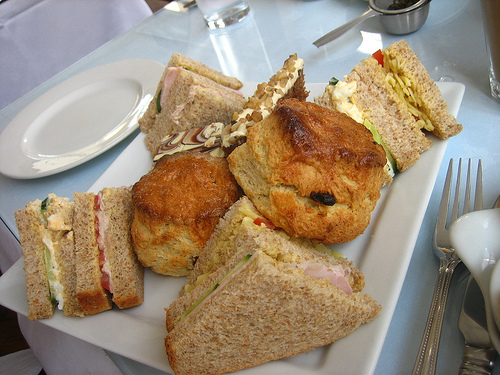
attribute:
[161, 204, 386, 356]
sandwich — triangle shaped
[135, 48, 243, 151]
sandwich — triangle shaped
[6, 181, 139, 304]
sandwich — triangle shaped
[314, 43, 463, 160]
sandwich — triangle shaped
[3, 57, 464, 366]
plate — square, rectangular, white, squre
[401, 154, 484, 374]
fork — metallic, silver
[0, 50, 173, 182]
plate — round, ceramic, empty, white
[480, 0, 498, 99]
glass — clear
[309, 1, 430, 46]
scoop — silver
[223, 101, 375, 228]
biscuit — round, next, tilted, brown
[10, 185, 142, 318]
sanwich — cut, quartered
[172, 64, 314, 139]
dessert — marbled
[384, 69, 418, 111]
pastry — golden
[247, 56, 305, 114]
cake — frosted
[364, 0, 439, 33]
container — steel